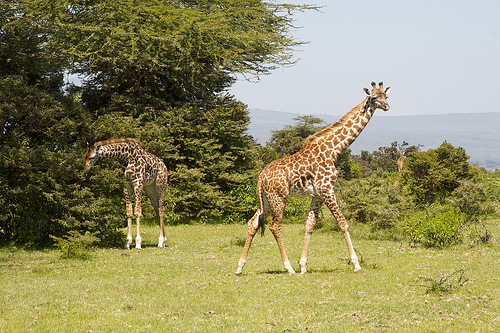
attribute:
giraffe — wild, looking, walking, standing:
[215, 74, 399, 291]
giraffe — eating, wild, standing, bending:
[72, 127, 180, 256]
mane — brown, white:
[286, 93, 367, 145]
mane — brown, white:
[89, 135, 140, 148]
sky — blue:
[267, 10, 499, 115]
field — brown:
[4, 215, 499, 331]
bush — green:
[71, 107, 250, 235]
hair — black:
[257, 213, 271, 235]